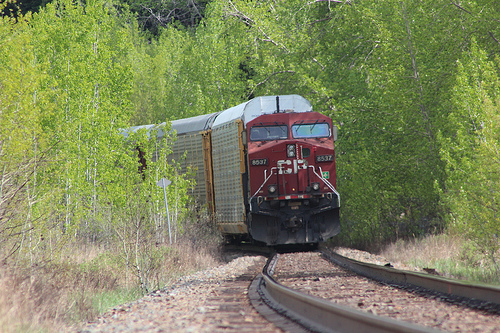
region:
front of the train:
[233, 77, 371, 255]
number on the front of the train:
[310, 150, 337, 172]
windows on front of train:
[242, 113, 334, 145]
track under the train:
[234, 238, 371, 313]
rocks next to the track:
[167, 274, 210, 315]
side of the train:
[180, 129, 242, 200]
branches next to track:
[53, 188, 183, 272]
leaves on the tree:
[293, 13, 411, 50]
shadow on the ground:
[382, 218, 430, 264]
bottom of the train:
[247, 200, 344, 255]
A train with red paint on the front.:
[116, 89, 343, 249]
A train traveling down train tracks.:
[119, 92, 498, 330]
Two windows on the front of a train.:
[244, 120, 333, 142]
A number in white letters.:
[246, 155, 270, 169]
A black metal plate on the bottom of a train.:
[244, 192, 343, 247]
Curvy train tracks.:
[250, 239, 497, 331]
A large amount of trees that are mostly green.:
[0, 1, 495, 246]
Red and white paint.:
[274, 191, 313, 203]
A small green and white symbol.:
[319, 168, 331, 182]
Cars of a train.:
[129, 109, 249, 240]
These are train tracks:
[239, 224, 446, 329]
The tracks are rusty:
[193, 196, 416, 308]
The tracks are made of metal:
[225, 208, 425, 310]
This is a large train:
[178, 125, 416, 281]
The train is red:
[243, 78, 468, 269]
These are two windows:
[209, 112, 391, 147]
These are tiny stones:
[103, 228, 185, 327]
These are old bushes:
[49, 122, 197, 219]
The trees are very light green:
[32, 133, 183, 258]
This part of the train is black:
[263, 205, 400, 300]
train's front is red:
[226, 80, 340, 250]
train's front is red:
[239, 108, 381, 293]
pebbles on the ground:
[135, 273, 212, 329]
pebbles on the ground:
[332, 278, 395, 318]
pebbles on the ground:
[212, 237, 257, 279]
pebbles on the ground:
[294, 258, 366, 310]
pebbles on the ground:
[161, 308, 199, 328]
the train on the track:
[119, 93, 341, 250]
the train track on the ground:
[222, 237, 498, 332]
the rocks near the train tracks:
[91, 241, 498, 332]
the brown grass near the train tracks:
[2, 226, 496, 331]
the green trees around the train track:
[0, 1, 498, 269]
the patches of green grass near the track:
[28, 243, 498, 332]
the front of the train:
[244, 112, 341, 242]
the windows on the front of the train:
[249, 124, 330, 139]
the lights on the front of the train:
[267, 184, 319, 194]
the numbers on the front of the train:
[250, 153, 332, 166]